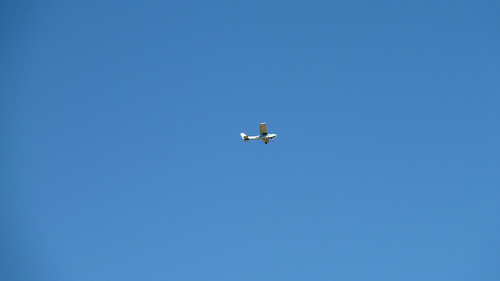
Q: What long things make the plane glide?
A: Wings.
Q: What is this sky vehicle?
A: Airplane.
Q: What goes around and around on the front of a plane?
A: Propeller.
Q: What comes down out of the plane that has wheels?
A: Landing gear.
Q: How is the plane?
A: In flight.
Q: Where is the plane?
A: In the sky.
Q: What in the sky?
A: An airplane.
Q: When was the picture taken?
A: Daytime.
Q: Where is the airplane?
A: In the sky.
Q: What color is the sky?
A: Blue.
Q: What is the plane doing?
A: Flying.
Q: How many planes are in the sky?
A: One.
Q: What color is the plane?
A: White.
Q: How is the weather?
A: Clear.